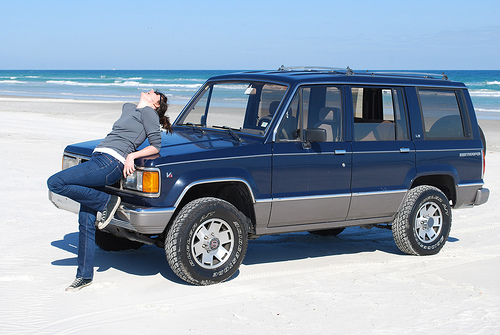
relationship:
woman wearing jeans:
[43, 87, 176, 298] [53, 150, 122, 279]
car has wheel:
[52, 65, 490, 284] [164, 197, 251, 285]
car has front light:
[52, 65, 490, 284] [118, 164, 164, 198]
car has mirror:
[52, 65, 490, 284] [298, 129, 328, 146]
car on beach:
[52, 65, 490, 284] [4, 97, 499, 329]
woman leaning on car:
[43, 87, 176, 298] [52, 65, 490, 284]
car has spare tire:
[52, 65, 490, 284] [426, 115, 488, 184]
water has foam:
[3, 70, 500, 121] [39, 80, 197, 89]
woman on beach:
[43, 87, 176, 298] [4, 97, 499, 329]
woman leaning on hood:
[43, 87, 176, 298] [94, 127, 255, 193]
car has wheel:
[52, 65, 490, 284] [397, 187, 450, 257]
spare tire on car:
[426, 115, 488, 184] [52, 65, 490, 284]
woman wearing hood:
[43, 87, 176, 298] [94, 105, 163, 167]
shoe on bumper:
[91, 196, 125, 226] [42, 178, 176, 233]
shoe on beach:
[65, 275, 92, 295] [4, 97, 499, 329]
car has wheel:
[52, 65, 490, 284] [96, 225, 145, 248]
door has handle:
[264, 88, 371, 239] [330, 146, 349, 155]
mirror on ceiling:
[243, 82, 263, 98] [210, 77, 467, 96]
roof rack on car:
[274, 59, 357, 76] [52, 65, 490, 284]